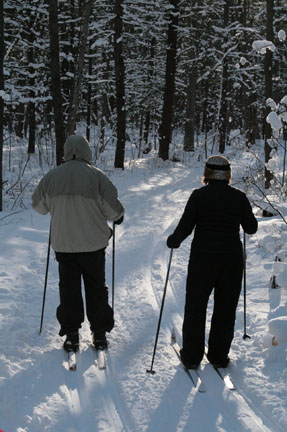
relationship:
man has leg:
[30, 122, 126, 353] [52, 248, 88, 341]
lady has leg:
[167, 154, 260, 367] [183, 255, 208, 369]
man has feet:
[30, 122, 126, 353] [61, 329, 112, 350]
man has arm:
[30, 122, 126, 353] [99, 168, 126, 230]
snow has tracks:
[5, 127, 286, 430] [66, 234, 271, 428]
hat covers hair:
[202, 154, 233, 185] [201, 174, 238, 188]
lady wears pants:
[167, 154, 260, 367] [181, 259, 239, 365]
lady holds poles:
[167, 154, 260, 367] [148, 237, 254, 373]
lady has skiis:
[167, 154, 260, 367] [171, 323, 240, 394]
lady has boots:
[167, 154, 260, 367] [183, 341, 234, 371]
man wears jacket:
[30, 122, 126, 353] [32, 135, 125, 250]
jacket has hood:
[32, 135, 125, 250] [59, 130, 98, 165]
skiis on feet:
[171, 323, 240, 394] [172, 341, 241, 370]